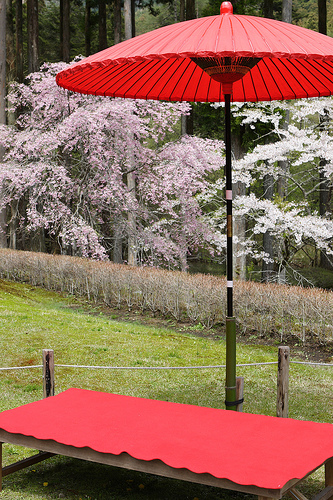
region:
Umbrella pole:
[220, 92, 241, 411]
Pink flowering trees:
[0, 46, 332, 288]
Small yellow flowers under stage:
[30, 463, 148, 494]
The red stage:
[1, 385, 332, 492]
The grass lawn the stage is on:
[0, 279, 330, 499]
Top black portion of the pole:
[216, 94, 234, 191]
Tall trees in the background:
[0, 0, 332, 284]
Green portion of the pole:
[224, 314, 241, 414]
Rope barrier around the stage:
[0, 358, 332, 373]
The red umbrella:
[46, 0, 331, 101]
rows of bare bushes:
[6, 237, 306, 354]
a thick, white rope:
[71, 357, 216, 375]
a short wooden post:
[36, 338, 69, 419]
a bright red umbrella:
[43, 3, 330, 109]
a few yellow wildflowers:
[123, 477, 153, 494]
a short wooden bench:
[4, 381, 329, 496]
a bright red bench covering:
[4, 376, 327, 493]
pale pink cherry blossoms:
[3, 70, 202, 271]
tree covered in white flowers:
[219, 94, 328, 286]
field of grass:
[9, 316, 116, 341]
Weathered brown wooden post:
[30, 319, 65, 418]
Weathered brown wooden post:
[273, 330, 306, 436]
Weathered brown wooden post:
[229, 371, 260, 416]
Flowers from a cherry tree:
[130, 126, 231, 198]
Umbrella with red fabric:
[40, 5, 330, 420]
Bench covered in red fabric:
[3, 379, 331, 498]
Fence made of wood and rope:
[1, 342, 331, 413]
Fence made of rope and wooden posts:
[1, 348, 332, 417]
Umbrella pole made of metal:
[198, 80, 260, 415]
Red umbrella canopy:
[16, 0, 331, 118]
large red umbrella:
[58, 5, 331, 107]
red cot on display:
[2, 377, 329, 497]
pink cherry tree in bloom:
[0, 55, 217, 281]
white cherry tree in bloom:
[214, 94, 332, 282]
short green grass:
[0, 272, 332, 498]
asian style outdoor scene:
[1, 0, 331, 498]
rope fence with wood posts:
[2, 329, 332, 434]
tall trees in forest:
[2, 1, 332, 288]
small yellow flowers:
[27, 465, 54, 498]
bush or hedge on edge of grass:
[2, 247, 332, 347]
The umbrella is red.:
[44, 0, 331, 411]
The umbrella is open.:
[50, 1, 331, 115]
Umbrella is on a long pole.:
[215, 89, 248, 416]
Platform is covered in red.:
[1, 384, 331, 494]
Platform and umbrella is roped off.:
[0, 338, 332, 423]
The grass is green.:
[1, 280, 330, 499]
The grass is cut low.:
[2, 292, 332, 498]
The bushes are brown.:
[1, 244, 332, 360]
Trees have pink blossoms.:
[0, 50, 218, 273]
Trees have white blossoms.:
[205, 91, 332, 287]